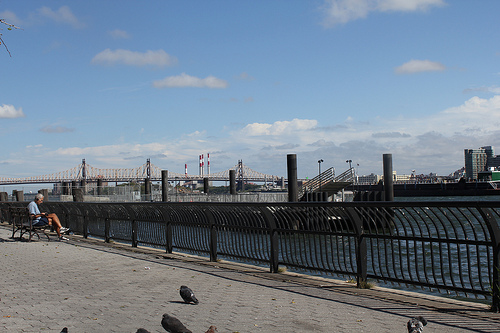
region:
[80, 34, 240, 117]
thin small white clouds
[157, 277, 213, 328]
brown pigeons on a walkway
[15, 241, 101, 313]
gray cobblestone walkway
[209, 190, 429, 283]
black iron curved fencing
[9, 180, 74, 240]
an elderly man sitting on a bench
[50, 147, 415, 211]
a long gray barge on the water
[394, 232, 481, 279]
blue river water behind black fence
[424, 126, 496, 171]
tall skyscrapers on the distance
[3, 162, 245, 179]
white railing along a bridge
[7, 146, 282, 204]
a bridge crossing a river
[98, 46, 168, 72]
a very white thick cloud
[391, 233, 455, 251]
a black gated iron fence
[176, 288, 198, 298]
a black bird walking around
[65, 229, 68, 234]
man is wearing tennis shoes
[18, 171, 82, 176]
a long wide bridge above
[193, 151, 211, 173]
flags swinging from a pole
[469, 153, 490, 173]
tall buildins standing across the way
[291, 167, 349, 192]
black steps behide the fence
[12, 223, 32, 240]
man is sitting on a bench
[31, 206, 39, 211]
man is wearing a blue polo shirt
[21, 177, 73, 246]
the man is sitting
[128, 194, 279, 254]
the railing is black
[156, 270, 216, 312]
the bird is on the walkway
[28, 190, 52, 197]
the hair is gray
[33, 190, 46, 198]
the man has hair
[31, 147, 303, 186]
the bridge is big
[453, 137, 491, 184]
the building is tall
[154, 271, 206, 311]
the bird is black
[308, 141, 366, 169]
the lights are off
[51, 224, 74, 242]
the sneaker is white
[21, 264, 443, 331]
Birds eating on sidewalk.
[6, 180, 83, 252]
Man sitting on a bench.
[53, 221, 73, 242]
Man's tennis shoes.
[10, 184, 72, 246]
Man with white hair.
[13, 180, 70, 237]
Man wearing a short sleeve shirt.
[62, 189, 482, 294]
Black iron safety fence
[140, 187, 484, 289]
A large body of water.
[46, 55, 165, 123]
The sky is blue.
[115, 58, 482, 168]
Clouds in the sky.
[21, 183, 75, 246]
Man is in the background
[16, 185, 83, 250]
Man is sitting down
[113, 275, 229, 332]
Birds are in the foreground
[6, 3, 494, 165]
Clouds are in the sky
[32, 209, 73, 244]
Man is wearing shorts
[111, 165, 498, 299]
A large body of water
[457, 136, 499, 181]
Building is in the background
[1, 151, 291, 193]
Bridge is in the background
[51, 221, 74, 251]
Man is wearing tennis shoes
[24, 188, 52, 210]
Man's hair is gray